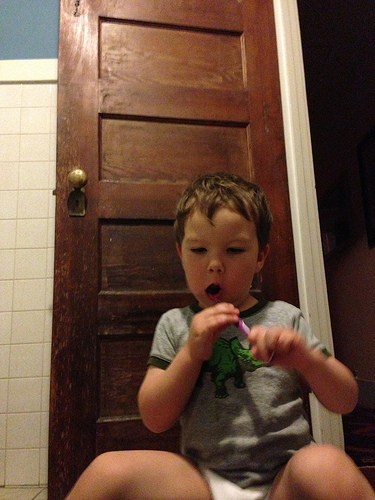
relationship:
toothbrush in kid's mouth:
[208, 288, 257, 340] [129, 162, 313, 369]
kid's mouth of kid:
[204, 278, 224, 302] [62, 171, 373, 498]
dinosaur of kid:
[196, 335, 268, 399] [62, 171, 373, 498]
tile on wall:
[0, 81, 56, 485] [0, 0, 60, 486]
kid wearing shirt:
[62, 171, 373, 498] [144, 295, 329, 487]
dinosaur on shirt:
[196, 335, 268, 399] [144, 295, 329, 487]